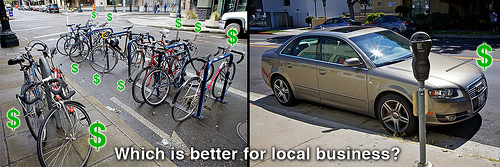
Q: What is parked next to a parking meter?
A: A car.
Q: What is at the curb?
A: Bicycles.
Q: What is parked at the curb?
A: A sedan.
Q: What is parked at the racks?
A: Bicycles.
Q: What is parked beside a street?
A: A car.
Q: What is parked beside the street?
A: Bikes.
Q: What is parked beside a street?
A: Bikes.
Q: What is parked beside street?
A: Silver car.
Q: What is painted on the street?
A: White arrow.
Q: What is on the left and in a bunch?
A: Bikes.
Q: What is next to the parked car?
A: Parking meter.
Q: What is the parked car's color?
A: Gold.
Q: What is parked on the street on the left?
A: Bikes.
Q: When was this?
A: Daytime.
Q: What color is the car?
A: Grey.